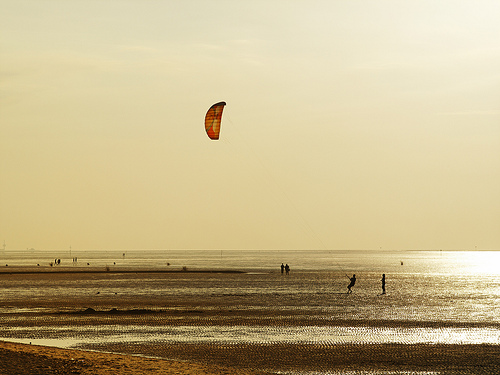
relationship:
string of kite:
[222, 112, 347, 276] [203, 101, 227, 141]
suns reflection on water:
[366, 226, 484, 289] [192, 271, 390, 358]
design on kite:
[205, 110, 219, 131] [198, 95, 230, 147]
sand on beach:
[40, 330, 94, 370] [43, 295, 247, 364]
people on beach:
[341, 266, 357, 296] [1, 250, 497, 374]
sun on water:
[416, 249, 498, 278] [3, 252, 497, 373]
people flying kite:
[347, 274, 357, 295] [196, 95, 346, 287]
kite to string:
[203, 101, 227, 142] [219, 121, 356, 279]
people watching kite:
[380, 273, 386, 294] [200, 97, 230, 142]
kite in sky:
[203, 101, 227, 141] [1, 0, 499, 250]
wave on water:
[21, 316, 496, 328] [3, 252, 497, 373]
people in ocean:
[340, 267, 406, 305] [1, 247, 499, 373]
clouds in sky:
[367, 28, 496, 144] [1, 0, 499, 250]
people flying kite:
[347, 274, 357, 295] [202, 99, 225, 139]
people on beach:
[255, 240, 308, 291] [1, 250, 497, 374]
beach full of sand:
[3, 272, 498, 371] [5, 252, 499, 369]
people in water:
[380, 273, 386, 294] [276, 302, 494, 368]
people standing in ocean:
[279, 260, 288, 270] [7, 247, 497, 349]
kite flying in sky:
[203, 101, 227, 141] [1, 0, 499, 250]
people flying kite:
[347, 274, 357, 295] [203, 101, 227, 141]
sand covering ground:
[0, 339, 249, 375] [5, 330, 498, 365]